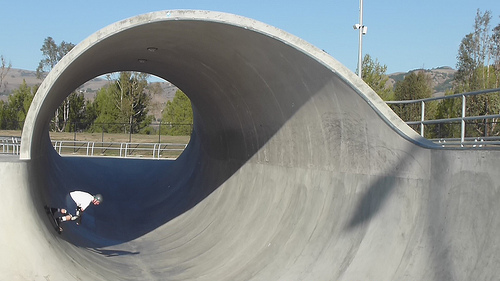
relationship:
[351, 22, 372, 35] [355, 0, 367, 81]
lights on pole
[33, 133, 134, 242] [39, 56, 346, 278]
person on ramp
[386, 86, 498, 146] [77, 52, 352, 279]
metal fence surrounding cylinder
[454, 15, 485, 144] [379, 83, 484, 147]
tree behind fence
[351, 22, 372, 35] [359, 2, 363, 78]
lights on pole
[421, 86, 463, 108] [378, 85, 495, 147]
pole on fence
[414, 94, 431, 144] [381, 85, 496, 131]
pole on fence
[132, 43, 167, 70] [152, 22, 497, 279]
lights on top of stone skate ramp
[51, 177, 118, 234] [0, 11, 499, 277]
skateboarder on ramp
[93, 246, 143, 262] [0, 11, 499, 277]
shadow from ramp